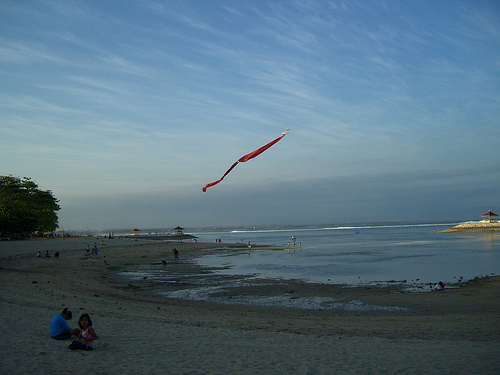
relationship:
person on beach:
[43, 297, 79, 342] [119, 233, 277, 356]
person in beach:
[43, 297, 79, 342] [119, 233, 277, 356]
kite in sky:
[212, 142, 266, 193] [287, 51, 455, 191]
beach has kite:
[119, 233, 277, 356] [212, 142, 266, 193]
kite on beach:
[212, 142, 266, 193] [119, 233, 277, 356]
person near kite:
[43, 297, 79, 342] [212, 142, 266, 193]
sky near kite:
[287, 51, 455, 191] [212, 142, 266, 193]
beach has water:
[119, 233, 277, 356] [310, 217, 406, 293]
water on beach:
[310, 217, 406, 293] [119, 233, 277, 356]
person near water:
[43, 297, 79, 342] [310, 217, 406, 293]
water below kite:
[310, 217, 406, 293] [212, 142, 266, 193]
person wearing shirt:
[58, 312, 104, 372] [50, 311, 112, 341]